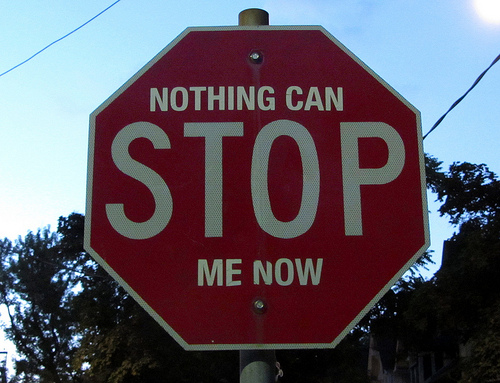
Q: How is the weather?
A: Clear.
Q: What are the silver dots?
A: Bolts.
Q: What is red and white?
A: A sign.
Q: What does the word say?
A: Stop.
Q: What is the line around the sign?
A: White line.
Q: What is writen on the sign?
A: Nothing can stop me now in white on sign.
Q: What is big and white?
A: Stop.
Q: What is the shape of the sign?
A: Octagon.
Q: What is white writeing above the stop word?
A: Nothing can.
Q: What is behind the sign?
A: Green trees.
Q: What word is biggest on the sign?
A: STOP.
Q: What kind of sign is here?
A: A stop sign.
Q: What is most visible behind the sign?
A: Trees.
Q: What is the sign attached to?
A: A pole.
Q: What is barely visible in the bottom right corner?
A: A house.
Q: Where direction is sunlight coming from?
A: The top right.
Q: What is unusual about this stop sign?
A: Other words have been added to it.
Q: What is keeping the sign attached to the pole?
A: The two screws.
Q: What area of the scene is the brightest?
A: The middle left edge.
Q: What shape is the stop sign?
A: An octagon.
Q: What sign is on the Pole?
A: Stop sign.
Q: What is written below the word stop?
A: Me now.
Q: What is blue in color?
A: Sky.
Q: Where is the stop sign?
A: On a pole.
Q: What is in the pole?
A: Sign board.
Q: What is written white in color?
A: Word nothing can stop me now.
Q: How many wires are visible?
A: Two.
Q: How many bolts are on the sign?
A: Two.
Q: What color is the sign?
A: Red.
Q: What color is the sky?
A: Blue.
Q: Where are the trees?
A: Background.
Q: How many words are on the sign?
A: Five.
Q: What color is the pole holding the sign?
A: Gray.